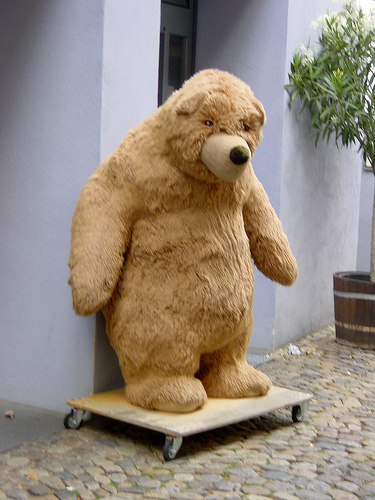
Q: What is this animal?
A: A bear.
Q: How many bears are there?
A: One.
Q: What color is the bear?
A: Brown.